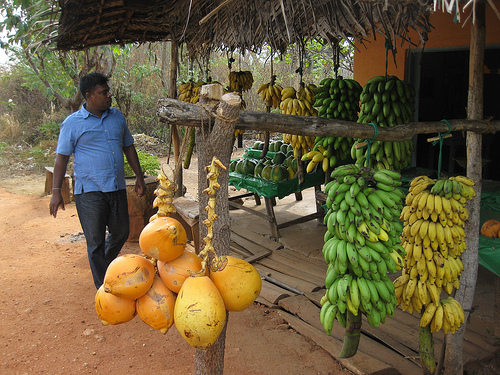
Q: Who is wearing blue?
A: Man.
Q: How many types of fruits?
A: 2.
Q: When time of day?
A: Daytime.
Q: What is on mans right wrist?
A: Watch.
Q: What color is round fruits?
A: Yellow.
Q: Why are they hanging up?
A: To sale.